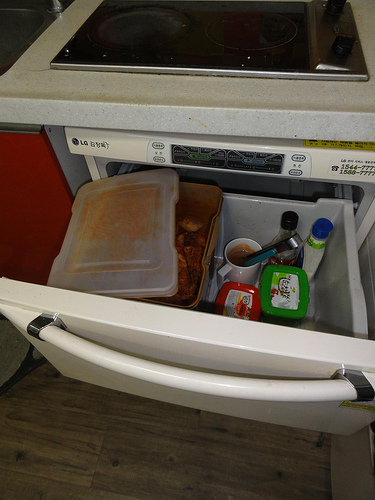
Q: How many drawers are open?
A: One.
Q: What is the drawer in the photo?
A: Refrigerator.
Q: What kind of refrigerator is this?
A: Mini refrigerator.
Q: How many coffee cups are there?
A: One.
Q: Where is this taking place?
A: In a kitchen.